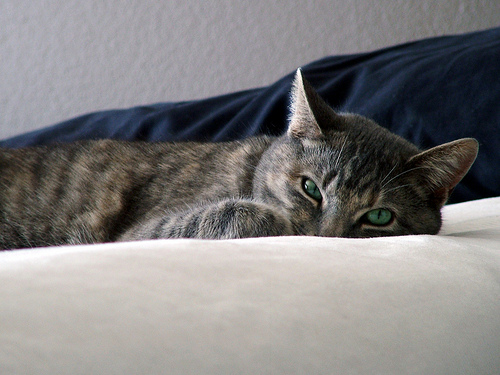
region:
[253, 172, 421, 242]
green eyes of a cat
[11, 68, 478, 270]
cat laying on a bed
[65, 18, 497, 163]
dark blue cover behnd cat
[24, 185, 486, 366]
a white blanket in front of cat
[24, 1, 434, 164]
wall behind a gray cat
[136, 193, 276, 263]
a gray cat leg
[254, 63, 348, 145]
right cat ear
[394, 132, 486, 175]
left cat ear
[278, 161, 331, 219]
right green cat eye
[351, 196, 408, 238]
left green cat eye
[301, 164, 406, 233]
cat has green eyes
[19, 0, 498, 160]
blanket is blue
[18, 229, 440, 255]
cat is lying down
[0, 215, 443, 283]
cat is on the bed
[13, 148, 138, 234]
cat has stripes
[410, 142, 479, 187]
cat has hair in it's ear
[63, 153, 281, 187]
cat is black and brown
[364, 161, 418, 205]
eye lashes are white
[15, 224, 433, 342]
bed cover is white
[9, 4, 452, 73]
wall is textured white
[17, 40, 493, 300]
A cat is resting on a sofa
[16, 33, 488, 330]
A cat is waiting for his master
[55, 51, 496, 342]
A cat is looking for mice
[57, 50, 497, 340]
A cat is looking for its food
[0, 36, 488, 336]
A cat is purring loudly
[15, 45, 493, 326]
A cat is enjoying a nap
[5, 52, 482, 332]
The cat is wanting to play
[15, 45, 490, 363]
The cat is enjoying its day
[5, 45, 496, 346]
The cat wants it's catnip toy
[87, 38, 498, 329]
The cat has green eyes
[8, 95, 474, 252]
cat is lying down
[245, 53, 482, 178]
cat has dark grey ears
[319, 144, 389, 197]
dark grey streaks near cat's eyes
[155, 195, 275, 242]
cat has dark grey paws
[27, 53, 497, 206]
cat in front of blue pillow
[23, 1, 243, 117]
white wall behind pillow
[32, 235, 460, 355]
blanket is light grey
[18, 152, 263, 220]
brown fur on cat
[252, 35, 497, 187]
blue pillow on bed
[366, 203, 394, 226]
left kitty eye on face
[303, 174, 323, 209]
right kitty eye on face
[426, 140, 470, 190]
left kitty ear on head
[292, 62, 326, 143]
right kitty ear on head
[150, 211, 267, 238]
right kitty front leg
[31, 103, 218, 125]
blue blanket on bed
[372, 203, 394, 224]
green kitty eye on face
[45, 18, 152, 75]
wall behind the bed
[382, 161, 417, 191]
whiskers on kitty face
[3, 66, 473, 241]
kitty laying on bed